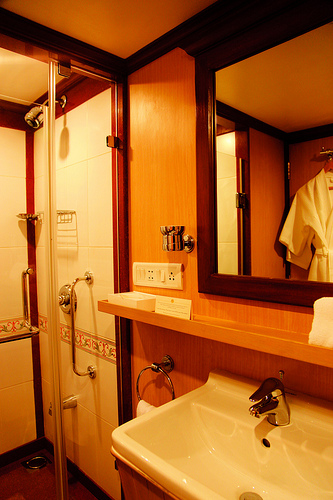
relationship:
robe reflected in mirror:
[277, 168, 332, 284] [212, 21, 333, 283]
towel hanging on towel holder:
[135, 397, 157, 416] [135, 353, 176, 403]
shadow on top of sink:
[252, 415, 278, 440] [111, 367, 332, 500]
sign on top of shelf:
[154, 295, 194, 322] [97, 297, 333, 369]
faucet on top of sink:
[246, 377, 291, 427] [111, 367, 332, 500]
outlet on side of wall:
[130, 263, 183, 290] [126, 46, 333, 419]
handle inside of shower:
[68, 270, 97, 380] [0, 75, 125, 499]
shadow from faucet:
[252, 415, 278, 440] [246, 377, 291, 427]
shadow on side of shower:
[58, 107, 72, 162] [0, 75, 125, 499]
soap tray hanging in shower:
[17, 208, 77, 220] [0, 75, 125, 499]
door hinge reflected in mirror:
[285, 161, 292, 182] [212, 21, 333, 283]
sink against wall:
[111, 367, 332, 500] [126, 46, 333, 419]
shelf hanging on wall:
[97, 297, 333, 369] [126, 46, 333, 419]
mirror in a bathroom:
[212, 21, 333, 283] [1, 0, 330, 498]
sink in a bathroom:
[111, 367, 332, 500] [1, 0, 330, 498]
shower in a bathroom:
[0, 75, 125, 499] [1, 0, 330, 498]